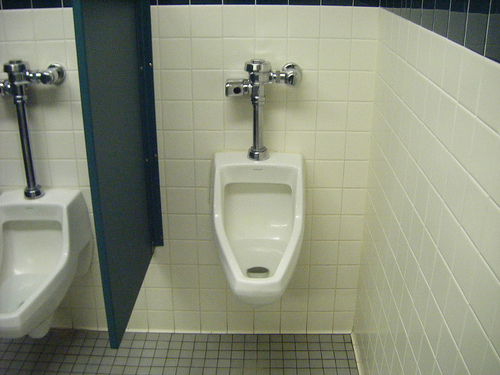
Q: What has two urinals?
A: The men's bathroom.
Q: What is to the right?
A: The higher up urinal.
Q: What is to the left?
A: The lower to the ground urinal.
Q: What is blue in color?
A: The divider between urinals.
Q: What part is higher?
A: The porcelain section of the urinal.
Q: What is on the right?
A: The urinal.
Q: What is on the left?
A: The urinal.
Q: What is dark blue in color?
A: The divider between the urinals.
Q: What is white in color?
A: The tile on the walls.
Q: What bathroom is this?
A: Men's.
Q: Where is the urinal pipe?
A: Bathroom.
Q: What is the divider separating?
A: Urinals.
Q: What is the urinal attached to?
A: Wall.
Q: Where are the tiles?
A: Wall.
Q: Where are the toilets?
A: On wall.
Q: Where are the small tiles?
A: Bathroom floor.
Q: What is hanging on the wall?
A: Toilet.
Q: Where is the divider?
A: Between the toilets.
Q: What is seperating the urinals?
A: A blue wall.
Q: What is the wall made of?
A: Tiles.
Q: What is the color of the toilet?
A: White.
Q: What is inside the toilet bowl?
A: Water.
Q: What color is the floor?
A: Grey.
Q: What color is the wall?
A: White.